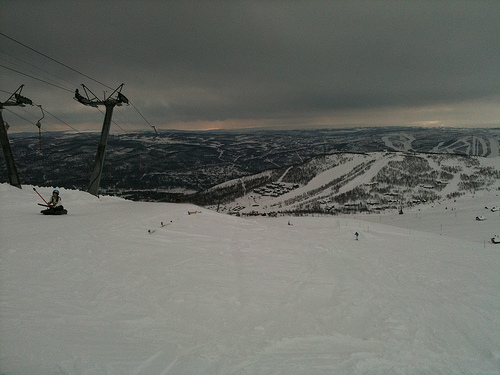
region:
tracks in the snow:
[373, 125, 498, 194]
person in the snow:
[28, 182, 72, 237]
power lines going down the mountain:
[30, 52, 142, 173]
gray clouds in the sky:
[265, 73, 372, 104]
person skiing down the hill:
[326, 219, 388, 260]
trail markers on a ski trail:
[141, 200, 218, 252]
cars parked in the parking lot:
[453, 197, 498, 244]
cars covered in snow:
[466, 177, 499, 247]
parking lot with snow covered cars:
[248, 176, 302, 204]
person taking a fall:
[14, 178, 84, 237]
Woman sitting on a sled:
[28, 176, 73, 223]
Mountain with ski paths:
[181, 102, 489, 257]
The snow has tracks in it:
[127, 253, 372, 372]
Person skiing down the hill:
[341, 217, 382, 266]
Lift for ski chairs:
[12, 79, 197, 194]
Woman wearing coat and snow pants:
[10, 172, 85, 233]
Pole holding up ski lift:
[67, 85, 124, 205]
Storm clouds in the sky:
[256, 55, 359, 116]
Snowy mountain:
[208, 208, 448, 357]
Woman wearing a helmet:
[46, 185, 66, 199]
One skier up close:
[23, 180, 83, 225]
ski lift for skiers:
[3, 36, 168, 192]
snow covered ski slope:
[5, 180, 496, 367]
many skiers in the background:
[15, 56, 495, 296]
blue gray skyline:
[0, 15, 490, 135]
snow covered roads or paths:
[201, 122, 497, 247]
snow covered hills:
[13, 123, 493, 185]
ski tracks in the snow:
[100, 210, 455, 355]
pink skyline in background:
[20, 105, 460, 135]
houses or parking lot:
[242, 175, 304, 203]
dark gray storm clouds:
[111, 8, 413, 121]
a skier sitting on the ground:
[23, 177, 89, 232]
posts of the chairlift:
[60, 72, 137, 192]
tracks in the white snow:
[215, 269, 416, 371]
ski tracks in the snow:
[375, 120, 498, 174]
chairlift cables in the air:
[5, 31, 115, 93]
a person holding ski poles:
[25, 180, 54, 212]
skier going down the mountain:
[346, 224, 369, 245]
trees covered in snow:
[136, 138, 286, 213]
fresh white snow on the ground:
[23, 237, 111, 339]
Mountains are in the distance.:
[0, 112, 498, 373]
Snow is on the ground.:
[104, 272, 244, 357]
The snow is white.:
[145, 258, 287, 335]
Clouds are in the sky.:
[154, 10, 397, 79]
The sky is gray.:
[152, 10, 402, 80]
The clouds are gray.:
[162, 15, 403, 93]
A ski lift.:
[2, 26, 142, 193]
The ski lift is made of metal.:
[2, 24, 134, 201]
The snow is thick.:
[146, 275, 406, 365]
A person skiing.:
[22, 177, 84, 233]